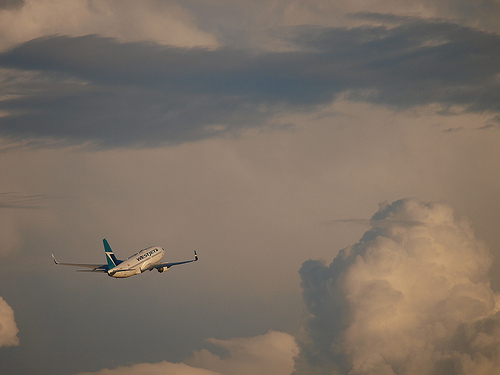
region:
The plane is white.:
[25, 217, 265, 321]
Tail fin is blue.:
[31, 210, 210, 310]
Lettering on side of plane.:
[29, 228, 221, 300]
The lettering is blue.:
[33, 223, 218, 304]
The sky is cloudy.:
[1, 2, 497, 372]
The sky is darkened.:
[2, 3, 499, 372]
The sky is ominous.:
[1, 2, 496, 373]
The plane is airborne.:
[25, 203, 263, 321]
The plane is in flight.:
[15, 145, 281, 340]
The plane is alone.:
[8, 62, 496, 354]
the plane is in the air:
[51, 236, 208, 282]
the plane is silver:
[43, 234, 205, 301]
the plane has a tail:
[98, 235, 124, 280]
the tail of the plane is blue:
[93, 233, 123, 277]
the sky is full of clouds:
[1, 195, 498, 374]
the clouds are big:
[2, 194, 499, 374]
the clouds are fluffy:
[0, 195, 499, 374]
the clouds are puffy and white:
[1, 194, 499, 373]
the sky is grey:
[1, 0, 496, 373]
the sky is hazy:
[1, 1, 498, 373]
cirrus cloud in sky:
[426, 120, 461, 139]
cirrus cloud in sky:
[309, 106, 359, 133]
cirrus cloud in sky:
[271, 126, 296, 141]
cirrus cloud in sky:
[0, 197, 57, 217]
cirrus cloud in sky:
[329, 213, 368, 225]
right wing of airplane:
[159, 250, 209, 277]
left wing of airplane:
[46, 247, 103, 277]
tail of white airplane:
[97, 237, 117, 262]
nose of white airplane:
[147, 242, 169, 264]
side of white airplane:
[109, 268, 135, 278]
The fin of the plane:
[97, 237, 125, 269]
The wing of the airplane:
[144, 249, 211, 281]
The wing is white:
[44, 250, 104, 282]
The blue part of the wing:
[148, 255, 203, 275]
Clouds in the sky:
[285, 175, 495, 370]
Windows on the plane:
[147, 250, 162, 260]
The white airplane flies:
[45, 230, 210, 290]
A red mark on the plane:
[125, 261, 130, 266]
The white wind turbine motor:
[155, 260, 170, 270]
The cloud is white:
[357, 270, 437, 361]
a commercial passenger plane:
[49, 237, 198, 277]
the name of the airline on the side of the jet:
[135, 247, 160, 262]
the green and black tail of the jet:
[100, 238, 120, 270]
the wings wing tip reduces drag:
[191, 245, 198, 262]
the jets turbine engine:
[157, 261, 169, 271]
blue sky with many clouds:
[0, 0, 499, 214]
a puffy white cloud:
[299, 199, 499, 373]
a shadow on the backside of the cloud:
[298, 190, 404, 374]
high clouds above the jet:
[0, 1, 498, 133]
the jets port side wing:
[50, 254, 106, 267]